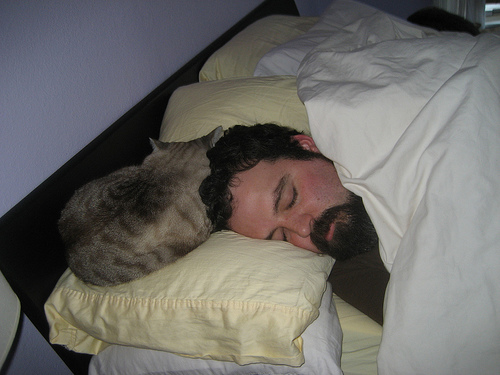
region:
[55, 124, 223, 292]
a cat sleeping by a man's head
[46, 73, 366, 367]
a pale yellow pillow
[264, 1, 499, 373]
a pale yellow sheet pulled over a man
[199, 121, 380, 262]
a man in bed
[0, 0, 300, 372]
the headboard of a bed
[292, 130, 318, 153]
the ear of a man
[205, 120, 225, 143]
the ear of a cat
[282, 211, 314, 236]
the nose of a man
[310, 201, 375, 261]
the moustache and beard of a man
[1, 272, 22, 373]
a lamp shade next to a bed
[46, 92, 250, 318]
this is a cat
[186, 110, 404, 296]
this is a man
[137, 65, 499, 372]
a man is sleeping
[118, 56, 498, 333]
man his laying in a bed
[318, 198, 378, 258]
man has a brown beard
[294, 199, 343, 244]
man has a brown mustache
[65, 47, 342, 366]
cat laying on a pillow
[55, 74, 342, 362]
bed pillow is tan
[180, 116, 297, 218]
man has brown hair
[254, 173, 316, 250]
man has eyes closed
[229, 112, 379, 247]
this is a man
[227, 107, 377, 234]
the man is sleeping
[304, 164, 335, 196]
the man is light skinned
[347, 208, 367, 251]
the man is beardy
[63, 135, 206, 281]
this is a cat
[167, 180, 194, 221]
the cat is grey in color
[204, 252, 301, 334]
this is the pillow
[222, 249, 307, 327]
the pillow is cream in color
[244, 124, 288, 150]
the hair is black in color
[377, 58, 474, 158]
this is a bedsheet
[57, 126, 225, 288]
A fat cat sleeping next to it's owner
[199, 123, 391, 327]
An adult man sleeping in bed next to his cat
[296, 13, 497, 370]
A cream colored blanket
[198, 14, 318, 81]
A yellow pillow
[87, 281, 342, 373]
A white pillow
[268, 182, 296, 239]
A man's closed eyes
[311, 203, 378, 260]
A man's goatee and beard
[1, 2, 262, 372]
A white, painted wall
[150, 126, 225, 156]
A cat's pointy ears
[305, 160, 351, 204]
A man's shaved cheek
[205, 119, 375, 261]
The head of a bearded man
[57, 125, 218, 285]
A grey and white cat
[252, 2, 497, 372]
A white blanket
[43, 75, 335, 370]
A yellow pillow case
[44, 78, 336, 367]
A cat on a bed pillow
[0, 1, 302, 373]
A black head board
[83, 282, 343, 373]
A white pillow case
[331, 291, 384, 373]
A yellow sheet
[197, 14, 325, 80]
An unoccupied pillow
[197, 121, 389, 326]
A sleeping man